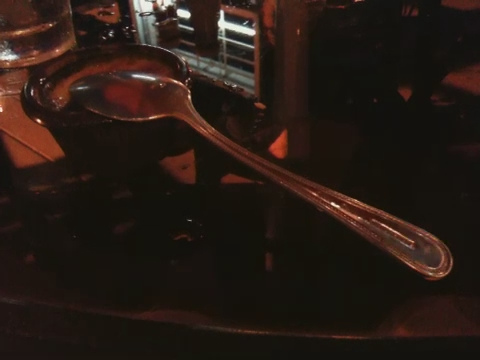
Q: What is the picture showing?
A: It is showing a place.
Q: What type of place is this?
A: It is a place.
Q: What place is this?
A: It is a place.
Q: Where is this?
A: This is at the place.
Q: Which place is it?
A: It is a place.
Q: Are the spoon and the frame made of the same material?
A: Yes, both the spoon and the frame are made of metal.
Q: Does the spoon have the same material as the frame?
A: Yes, both the spoon and the frame are made of metal.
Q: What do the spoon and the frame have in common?
A: The material, both the spoon and the frame are metallic.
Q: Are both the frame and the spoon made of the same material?
A: Yes, both the frame and the spoon are made of metal.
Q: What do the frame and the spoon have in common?
A: The material, both the frame and the spoon are metallic.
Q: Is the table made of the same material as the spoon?
A: No, the table is made of wood and the spoon is made of metal.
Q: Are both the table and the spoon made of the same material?
A: No, the table is made of wood and the spoon is made of metal.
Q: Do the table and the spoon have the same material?
A: No, the table is made of wood and the spoon is made of metal.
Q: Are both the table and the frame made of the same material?
A: No, the table is made of wood and the frame is made of metal.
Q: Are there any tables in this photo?
A: Yes, there is a table.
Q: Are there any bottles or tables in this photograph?
A: Yes, there is a table.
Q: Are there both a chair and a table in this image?
A: No, there is a table but no chairs.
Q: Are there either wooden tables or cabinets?
A: Yes, there is a wood table.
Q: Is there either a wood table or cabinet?
A: Yes, there is a wood table.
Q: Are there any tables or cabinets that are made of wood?
A: Yes, the table is made of wood.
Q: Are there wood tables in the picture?
A: Yes, there is a table that is made of wood.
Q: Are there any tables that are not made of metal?
A: Yes, there is a table that is made of wood.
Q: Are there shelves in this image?
A: No, there are no shelves.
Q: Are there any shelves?
A: No, there are no shelves.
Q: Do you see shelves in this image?
A: No, there are no shelves.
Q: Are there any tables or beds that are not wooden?
A: No, there is a table but it is wooden.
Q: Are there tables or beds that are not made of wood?
A: No, there is a table but it is made of wood.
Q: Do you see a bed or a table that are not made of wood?
A: No, there is a table but it is made of wood.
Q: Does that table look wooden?
A: Yes, the table is wooden.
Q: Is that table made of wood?
A: Yes, the table is made of wood.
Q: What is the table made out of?
A: The table is made of wood.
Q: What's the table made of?
A: The table is made of wood.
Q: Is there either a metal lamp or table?
A: No, there is a table but it is wooden.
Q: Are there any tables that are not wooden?
A: No, there is a table but it is wooden.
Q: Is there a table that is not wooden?
A: No, there is a table but it is wooden.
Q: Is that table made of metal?
A: No, the table is made of wood.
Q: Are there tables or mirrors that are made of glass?
A: No, there is a table but it is made of wood.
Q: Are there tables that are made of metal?
A: No, there is a table but it is made of wood.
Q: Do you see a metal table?
A: No, there is a table but it is made of wood.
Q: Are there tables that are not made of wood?
A: No, there is a table but it is made of wood.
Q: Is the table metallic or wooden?
A: The table is wooden.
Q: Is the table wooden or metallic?
A: The table is wooden.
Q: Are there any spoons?
A: Yes, there is a spoon.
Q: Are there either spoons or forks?
A: Yes, there is a spoon.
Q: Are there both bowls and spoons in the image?
A: Yes, there are both a spoon and a bowl.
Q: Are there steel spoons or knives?
A: Yes, there is a steel spoon.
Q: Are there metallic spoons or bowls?
A: Yes, there is a metal spoon.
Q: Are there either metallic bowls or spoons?
A: Yes, there is a metal spoon.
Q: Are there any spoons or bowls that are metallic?
A: Yes, the spoon is metallic.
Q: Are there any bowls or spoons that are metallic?
A: Yes, the spoon is metallic.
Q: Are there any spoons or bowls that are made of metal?
A: Yes, the spoon is made of metal.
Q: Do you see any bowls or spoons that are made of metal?
A: Yes, the spoon is made of metal.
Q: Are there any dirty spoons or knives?
A: Yes, there is a dirty spoon.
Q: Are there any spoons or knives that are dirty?
A: Yes, the spoon is dirty.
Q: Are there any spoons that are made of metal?
A: Yes, there is a spoon that is made of metal.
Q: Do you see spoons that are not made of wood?
A: Yes, there is a spoon that is made of metal.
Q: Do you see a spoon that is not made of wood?
A: Yes, there is a spoon that is made of metal.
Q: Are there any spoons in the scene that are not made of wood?
A: Yes, there is a spoon that is made of metal.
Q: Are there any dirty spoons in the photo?
A: Yes, there is a dirty spoon.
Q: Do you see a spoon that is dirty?
A: Yes, there is a spoon that is dirty.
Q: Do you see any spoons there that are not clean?
A: Yes, there is a dirty spoon.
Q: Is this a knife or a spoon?
A: This is a spoon.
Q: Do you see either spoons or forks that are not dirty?
A: No, there is a spoon but it is dirty.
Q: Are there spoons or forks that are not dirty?
A: No, there is a spoon but it is dirty.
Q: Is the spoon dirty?
A: Yes, the spoon is dirty.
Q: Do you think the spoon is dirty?
A: Yes, the spoon is dirty.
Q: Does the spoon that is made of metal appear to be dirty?
A: Yes, the spoon is dirty.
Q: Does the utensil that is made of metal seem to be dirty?
A: Yes, the spoon is dirty.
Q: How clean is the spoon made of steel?
A: The spoon is dirty.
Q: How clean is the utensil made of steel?
A: The spoon is dirty.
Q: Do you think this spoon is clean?
A: No, the spoon is dirty.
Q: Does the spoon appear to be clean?
A: No, the spoon is dirty.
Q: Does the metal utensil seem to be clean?
A: No, the spoon is dirty.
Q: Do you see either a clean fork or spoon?
A: No, there is a spoon but it is dirty.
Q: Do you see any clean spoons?
A: No, there is a spoon but it is dirty.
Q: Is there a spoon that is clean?
A: No, there is a spoon but it is dirty.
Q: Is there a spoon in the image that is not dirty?
A: No, there is a spoon but it is dirty.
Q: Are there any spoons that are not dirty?
A: No, there is a spoon but it is dirty.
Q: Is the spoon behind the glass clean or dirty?
A: The spoon is dirty.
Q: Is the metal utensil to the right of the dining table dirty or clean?
A: The spoon is dirty.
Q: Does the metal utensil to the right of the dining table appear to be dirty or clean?
A: The spoon is dirty.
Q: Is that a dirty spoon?
A: Yes, that is a dirty spoon.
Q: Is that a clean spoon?
A: No, that is a dirty spoon.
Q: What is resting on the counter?
A: The spoon is resting on the counter.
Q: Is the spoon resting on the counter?
A: Yes, the spoon is resting on the counter.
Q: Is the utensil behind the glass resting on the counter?
A: Yes, the spoon is resting on the counter.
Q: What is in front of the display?
A: The spoon is in front of the display.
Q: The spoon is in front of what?
A: The spoon is in front of the display.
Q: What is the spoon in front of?
A: The spoon is in front of the display.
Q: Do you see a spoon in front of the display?
A: Yes, there is a spoon in front of the display.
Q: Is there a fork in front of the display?
A: No, there is a spoon in front of the display.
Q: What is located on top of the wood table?
A: The spoon is on top of the table.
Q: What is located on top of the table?
A: The spoon is on top of the table.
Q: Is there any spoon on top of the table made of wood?
A: Yes, there is a spoon on top of the table.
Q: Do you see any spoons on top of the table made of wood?
A: Yes, there is a spoon on top of the table.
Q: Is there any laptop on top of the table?
A: No, there is a spoon on top of the table.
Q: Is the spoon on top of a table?
A: Yes, the spoon is on top of a table.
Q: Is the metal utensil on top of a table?
A: Yes, the spoon is on top of a table.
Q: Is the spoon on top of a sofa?
A: No, the spoon is on top of a table.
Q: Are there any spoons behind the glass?
A: Yes, there is a spoon behind the glass.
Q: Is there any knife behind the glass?
A: No, there is a spoon behind the glass.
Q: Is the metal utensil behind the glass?
A: Yes, the spoon is behind the glass.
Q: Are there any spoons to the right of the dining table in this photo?
A: Yes, there is a spoon to the right of the dining table.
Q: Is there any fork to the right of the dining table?
A: No, there is a spoon to the right of the dining table.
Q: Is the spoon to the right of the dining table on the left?
A: Yes, the spoon is to the right of the dining table.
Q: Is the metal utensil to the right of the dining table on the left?
A: Yes, the spoon is to the right of the dining table.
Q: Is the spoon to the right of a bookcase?
A: No, the spoon is to the right of the dining table.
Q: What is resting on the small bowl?
A: The spoon is resting on the bowl.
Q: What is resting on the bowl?
A: The spoon is resting on the bowl.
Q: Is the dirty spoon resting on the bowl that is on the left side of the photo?
A: Yes, the spoon is resting on the bowl.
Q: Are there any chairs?
A: No, there are no chairs.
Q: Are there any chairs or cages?
A: No, there are no chairs or cages.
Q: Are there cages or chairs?
A: No, there are no chairs or cages.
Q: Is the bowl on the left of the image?
A: Yes, the bowl is on the left of the image.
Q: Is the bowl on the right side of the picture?
A: No, the bowl is on the left of the image.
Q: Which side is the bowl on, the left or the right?
A: The bowl is on the left of the image.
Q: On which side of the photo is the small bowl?
A: The bowl is on the left of the image.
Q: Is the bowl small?
A: Yes, the bowl is small.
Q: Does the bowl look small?
A: Yes, the bowl is small.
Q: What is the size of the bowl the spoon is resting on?
A: The bowl is small.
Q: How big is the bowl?
A: The bowl is small.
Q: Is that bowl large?
A: No, the bowl is small.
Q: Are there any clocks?
A: No, there are no clocks.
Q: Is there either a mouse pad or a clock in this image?
A: No, there are no clocks or mouse pads.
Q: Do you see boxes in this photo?
A: No, there are no boxes.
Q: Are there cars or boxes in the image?
A: No, there are no boxes or cars.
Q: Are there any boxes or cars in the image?
A: No, there are no boxes or cars.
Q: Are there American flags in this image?
A: No, there are no American flags.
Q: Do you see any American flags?
A: No, there are no American flags.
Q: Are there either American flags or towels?
A: No, there are no American flags or towels.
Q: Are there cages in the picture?
A: No, there are no cages.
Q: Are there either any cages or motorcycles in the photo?
A: No, there are no cages or motorcycles.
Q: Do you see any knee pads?
A: No, there are no knee pads.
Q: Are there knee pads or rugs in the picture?
A: No, there are no knee pads or rugs.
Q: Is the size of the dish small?
A: Yes, the dish is small.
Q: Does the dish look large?
A: No, the dish is small.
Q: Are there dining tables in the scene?
A: Yes, there is a dining table.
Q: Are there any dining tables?
A: Yes, there is a dining table.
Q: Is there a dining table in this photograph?
A: Yes, there is a dining table.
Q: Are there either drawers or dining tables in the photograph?
A: Yes, there is a dining table.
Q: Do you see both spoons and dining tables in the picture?
A: Yes, there are both a dining table and a spoon.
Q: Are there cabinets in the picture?
A: No, there are no cabinets.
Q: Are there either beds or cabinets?
A: No, there are no cabinets or beds.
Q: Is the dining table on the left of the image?
A: Yes, the dining table is on the left of the image.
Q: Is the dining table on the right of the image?
A: No, the dining table is on the left of the image.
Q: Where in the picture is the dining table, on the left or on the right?
A: The dining table is on the left of the image.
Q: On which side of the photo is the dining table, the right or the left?
A: The dining table is on the left of the image.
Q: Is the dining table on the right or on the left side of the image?
A: The dining table is on the left of the image.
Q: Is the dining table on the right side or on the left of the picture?
A: The dining table is on the left of the image.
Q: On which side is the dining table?
A: The dining table is on the left of the image.